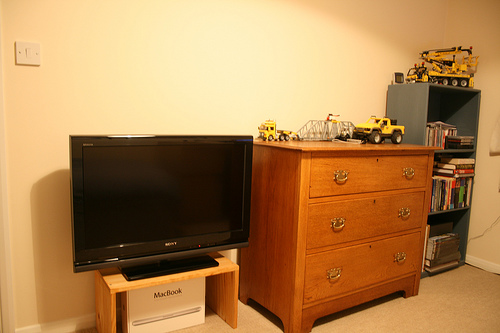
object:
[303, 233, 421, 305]
drawer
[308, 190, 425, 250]
drawer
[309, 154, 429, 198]
drawer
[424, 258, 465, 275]
shelf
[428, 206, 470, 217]
shelf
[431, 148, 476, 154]
shelf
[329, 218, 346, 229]
handles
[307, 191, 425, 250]
draw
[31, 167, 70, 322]
shadow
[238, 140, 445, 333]
furniture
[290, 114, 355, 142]
bridge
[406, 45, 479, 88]
truck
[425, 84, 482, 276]
dresser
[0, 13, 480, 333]
room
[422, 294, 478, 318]
carpet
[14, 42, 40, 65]
board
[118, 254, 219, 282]
stand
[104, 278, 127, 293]
table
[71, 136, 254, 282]
television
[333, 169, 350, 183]
handles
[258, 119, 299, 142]
truck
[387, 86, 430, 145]
shelf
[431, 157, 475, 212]
books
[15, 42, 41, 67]
plate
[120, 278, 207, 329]
laptop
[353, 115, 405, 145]
toy truck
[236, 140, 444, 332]
chest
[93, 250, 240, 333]
tv stand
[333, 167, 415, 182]
knobs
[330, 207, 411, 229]
knobs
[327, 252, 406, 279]
knobs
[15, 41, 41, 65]
light switch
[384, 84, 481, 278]
book shelf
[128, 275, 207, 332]
box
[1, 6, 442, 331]
wall